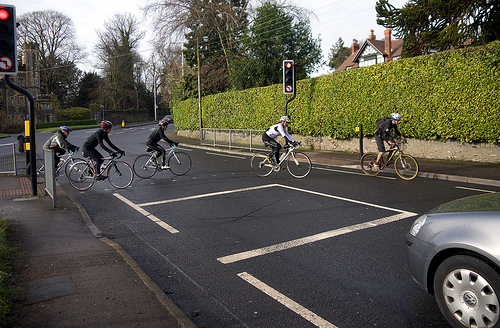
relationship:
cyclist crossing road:
[132, 121, 192, 180] [0, 120, 500, 328]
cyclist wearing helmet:
[360, 113, 418, 180] [389, 113, 402, 122]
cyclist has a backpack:
[373, 112, 407, 171] [374, 117, 391, 133]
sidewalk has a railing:
[178, 128, 499, 184] [198, 127, 279, 151]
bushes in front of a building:
[173, 40, 498, 137] [334, 25, 478, 73]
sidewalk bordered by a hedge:
[178, 128, 499, 184] [173, 40, 498, 137]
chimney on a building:
[382, 29, 392, 58] [334, 25, 478, 73]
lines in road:
[168, 182, 401, 300] [0, 120, 500, 328]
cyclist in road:
[82, 120, 126, 182] [0, 120, 500, 328]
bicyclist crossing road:
[249, 116, 311, 180] [0, 120, 500, 328]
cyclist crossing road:
[44, 125, 78, 152] [0, 120, 500, 328]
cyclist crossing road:
[360, 113, 418, 180] [0, 120, 500, 328]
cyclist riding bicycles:
[42, 125, 80, 169] [27, 150, 135, 190]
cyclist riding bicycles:
[373, 112, 407, 171] [249, 144, 418, 181]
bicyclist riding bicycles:
[261, 115, 300, 170] [132, 141, 311, 177]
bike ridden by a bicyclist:
[250, 144, 315, 178] [261, 115, 300, 170]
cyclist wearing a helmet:
[82, 120, 126, 182] [100, 120, 112, 129]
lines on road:
[114, 192, 183, 237] [73, 189, 444, 281]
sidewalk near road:
[178, 128, 499, 184] [73, 189, 444, 281]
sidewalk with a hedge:
[178, 128, 499, 184] [173, 40, 498, 137]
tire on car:
[442, 267, 498, 327] [405, 188, 499, 309]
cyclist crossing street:
[360, 113, 418, 180] [168, 182, 401, 300]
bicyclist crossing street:
[261, 115, 300, 170] [168, 182, 401, 300]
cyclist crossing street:
[132, 121, 192, 180] [168, 182, 401, 300]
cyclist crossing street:
[74, 120, 125, 183] [168, 182, 401, 300]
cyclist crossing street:
[44, 125, 78, 152] [168, 182, 401, 300]